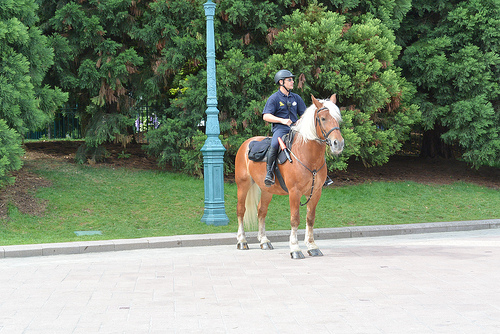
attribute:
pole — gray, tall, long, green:
[199, 1, 231, 232]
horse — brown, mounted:
[233, 90, 346, 263]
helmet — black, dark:
[272, 68, 297, 86]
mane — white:
[289, 98, 348, 146]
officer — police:
[262, 68, 309, 188]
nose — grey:
[327, 139, 347, 156]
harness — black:
[310, 106, 344, 141]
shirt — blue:
[261, 88, 308, 132]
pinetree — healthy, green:
[2, 1, 74, 194]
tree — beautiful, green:
[39, 0, 179, 165]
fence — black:
[25, 85, 207, 142]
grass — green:
[1, 154, 497, 244]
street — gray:
[2, 227, 498, 332]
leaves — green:
[115, 47, 147, 77]